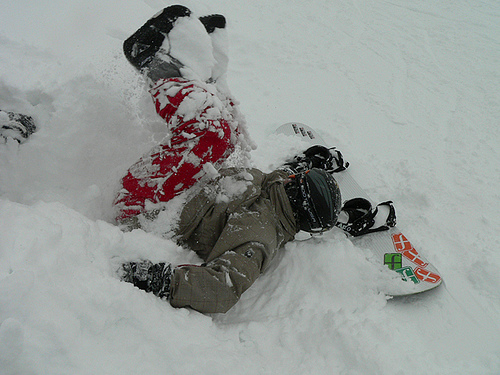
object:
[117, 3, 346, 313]
man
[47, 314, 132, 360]
snow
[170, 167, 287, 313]
jacket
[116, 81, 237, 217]
pants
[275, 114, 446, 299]
snowboard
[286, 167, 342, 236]
helmet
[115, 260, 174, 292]
glove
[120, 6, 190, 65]
shoes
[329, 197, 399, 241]
strap